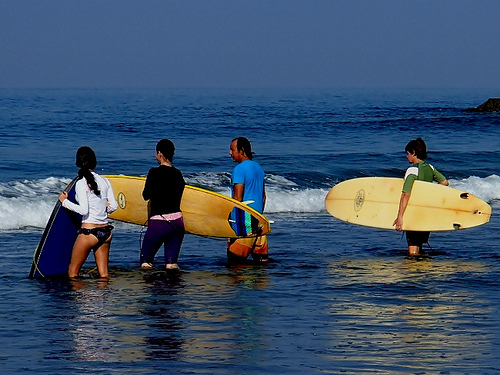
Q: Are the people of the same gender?
A: No, they are both male and female.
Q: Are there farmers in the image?
A: No, there are no farmers.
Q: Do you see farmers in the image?
A: No, there are no farmers.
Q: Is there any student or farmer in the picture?
A: No, there are no farmers or students.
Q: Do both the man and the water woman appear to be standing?
A: Yes, both the man and the woman are standing.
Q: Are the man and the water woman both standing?
A: Yes, both the man and the woman are standing.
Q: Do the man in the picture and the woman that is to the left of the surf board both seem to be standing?
A: Yes, both the man and the woman are standing.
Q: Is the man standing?
A: Yes, the man is standing.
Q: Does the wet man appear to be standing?
A: Yes, the man is standing.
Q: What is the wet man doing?
A: The man is standing.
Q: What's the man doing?
A: The man is standing.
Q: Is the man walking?
A: No, the man is standing.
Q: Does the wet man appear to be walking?
A: No, the man is standing.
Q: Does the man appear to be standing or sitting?
A: The man is standing.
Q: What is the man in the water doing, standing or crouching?
A: The man is standing.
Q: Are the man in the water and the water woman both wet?
A: Yes, both the man and the woman are wet.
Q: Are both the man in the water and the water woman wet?
A: Yes, both the man and the woman are wet.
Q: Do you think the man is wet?
A: Yes, the man is wet.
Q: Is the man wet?
A: Yes, the man is wet.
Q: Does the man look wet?
A: Yes, the man is wet.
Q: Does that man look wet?
A: Yes, the man is wet.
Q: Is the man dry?
A: No, the man is wet.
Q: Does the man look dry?
A: No, the man is wet.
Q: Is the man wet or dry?
A: The man is wet.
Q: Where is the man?
A: The man is in the water.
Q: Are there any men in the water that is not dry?
A: Yes, there is a man in the water.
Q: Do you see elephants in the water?
A: No, there is a man in the water.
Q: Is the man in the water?
A: Yes, the man is in the water.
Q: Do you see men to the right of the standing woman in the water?
A: Yes, there is a man to the right of the woman.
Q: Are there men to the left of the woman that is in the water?
A: No, the man is to the right of the woman.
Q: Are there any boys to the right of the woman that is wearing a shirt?
A: No, there is a man to the right of the woman.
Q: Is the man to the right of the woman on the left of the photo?
A: Yes, the man is to the right of the woman.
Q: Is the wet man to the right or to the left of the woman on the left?
A: The man is to the right of the woman.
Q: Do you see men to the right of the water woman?
A: Yes, there is a man to the right of the woman.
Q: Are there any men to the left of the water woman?
A: No, the man is to the right of the woman.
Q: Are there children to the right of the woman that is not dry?
A: No, there is a man to the right of the woman.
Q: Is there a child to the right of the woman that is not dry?
A: No, there is a man to the right of the woman.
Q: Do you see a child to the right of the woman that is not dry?
A: No, there is a man to the right of the woman.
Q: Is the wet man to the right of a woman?
A: Yes, the man is to the right of a woman.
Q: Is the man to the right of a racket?
A: No, the man is to the right of a woman.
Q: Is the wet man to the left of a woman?
A: No, the man is to the right of a woman.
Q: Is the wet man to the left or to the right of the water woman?
A: The man is to the right of the woman.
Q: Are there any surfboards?
A: Yes, there is a surfboard.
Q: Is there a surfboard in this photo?
A: Yes, there is a surfboard.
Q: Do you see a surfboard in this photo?
A: Yes, there is a surfboard.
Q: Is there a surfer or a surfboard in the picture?
A: Yes, there is a surfboard.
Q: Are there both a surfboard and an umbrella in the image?
A: No, there is a surfboard but no umbrellas.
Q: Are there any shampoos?
A: No, there are no shampoos.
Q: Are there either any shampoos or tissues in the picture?
A: No, there are no shampoos or tissues.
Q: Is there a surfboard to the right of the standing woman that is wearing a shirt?
A: Yes, there is a surfboard to the right of the woman.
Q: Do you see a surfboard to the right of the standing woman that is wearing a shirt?
A: Yes, there is a surfboard to the right of the woman.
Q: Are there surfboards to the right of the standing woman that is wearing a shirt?
A: Yes, there is a surfboard to the right of the woman.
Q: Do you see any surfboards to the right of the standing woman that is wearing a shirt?
A: Yes, there is a surfboard to the right of the woman.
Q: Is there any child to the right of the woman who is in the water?
A: No, there is a surfboard to the right of the woman.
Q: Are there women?
A: Yes, there is a woman.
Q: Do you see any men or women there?
A: Yes, there is a woman.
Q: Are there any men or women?
A: Yes, there is a woman.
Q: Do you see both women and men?
A: Yes, there are both a woman and a man.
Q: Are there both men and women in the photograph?
A: Yes, there are both a woman and a man.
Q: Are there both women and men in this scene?
A: Yes, there are both a woman and a man.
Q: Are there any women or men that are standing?
A: Yes, the woman is standing.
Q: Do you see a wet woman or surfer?
A: Yes, there is a wet woman.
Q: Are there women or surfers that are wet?
A: Yes, the woman is wet.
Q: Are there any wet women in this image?
A: Yes, there is a wet woman.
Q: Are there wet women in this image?
A: Yes, there is a wet woman.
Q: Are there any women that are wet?
A: Yes, there is a woman that is wet.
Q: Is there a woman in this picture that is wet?
A: Yes, there is a woman that is wet.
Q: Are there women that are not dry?
A: Yes, there is a wet woman.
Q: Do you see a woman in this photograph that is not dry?
A: Yes, there is a wet woman.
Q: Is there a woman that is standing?
A: Yes, there is a woman that is standing.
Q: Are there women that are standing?
A: Yes, there is a woman that is standing.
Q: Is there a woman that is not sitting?
A: Yes, there is a woman that is standing.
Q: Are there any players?
A: No, there are no players.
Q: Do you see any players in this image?
A: No, there are no players.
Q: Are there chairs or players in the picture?
A: No, there are no players or chairs.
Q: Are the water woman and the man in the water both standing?
A: Yes, both the woman and the man are standing.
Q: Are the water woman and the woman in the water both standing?
A: Yes, both the woman and the woman are standing.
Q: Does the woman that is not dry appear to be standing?
A: Yes, the woman is standing.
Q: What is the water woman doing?
A: The woman is standing.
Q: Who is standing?
A: The woman is standing.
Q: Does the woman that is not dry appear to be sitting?
A: No, the woman is standing.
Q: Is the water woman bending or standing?
A: The woman is standing.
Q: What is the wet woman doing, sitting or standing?
A: The woman is standing.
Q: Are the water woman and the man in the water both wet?
A: Yes, both the woman and the man are wet.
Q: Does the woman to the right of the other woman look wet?
A: Yes, the woman is wet.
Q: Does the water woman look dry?
A: No, the woman is wet.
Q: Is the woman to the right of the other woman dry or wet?
A: The woman is wet.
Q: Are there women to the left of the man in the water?
A: Yes, there is a woman to the left of the man.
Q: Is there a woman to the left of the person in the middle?
A: Yes, there is a woman to the left of the man.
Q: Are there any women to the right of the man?
A: No, the woman is to the left of the man.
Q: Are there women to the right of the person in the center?
A: No, the woman is to the left of the man.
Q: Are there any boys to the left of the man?
A: No, there is a woman to the left of the man.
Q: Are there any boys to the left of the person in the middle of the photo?
A: No, there is a woman to the left of the man.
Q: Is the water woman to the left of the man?
A: Yes, the woman is to the left of the man.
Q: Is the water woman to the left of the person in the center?
A: Yes, the woman is to the left of the man.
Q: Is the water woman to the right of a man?
A: No, the woman is to the left of a man.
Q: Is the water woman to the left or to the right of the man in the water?
A: The woman is to the left of the man.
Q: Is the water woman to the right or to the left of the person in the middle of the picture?
A: The woman is to the left of the man.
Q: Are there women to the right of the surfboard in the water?
A: Yes, there is a woman to the right of the surf board.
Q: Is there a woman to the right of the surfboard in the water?
A: Yes, there is a woman to the right of the surf board.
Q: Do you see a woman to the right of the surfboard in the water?
A: Yes, there is a woman to the right of the surf board.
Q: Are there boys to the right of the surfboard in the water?
A: No, there is a woman to the right of the surfboard.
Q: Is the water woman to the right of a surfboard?
A: Yes, the woman is to the right of a surfboard.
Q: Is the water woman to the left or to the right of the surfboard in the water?
A: The woman is to the right of the surfboard.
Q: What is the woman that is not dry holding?
A: The woman is holding the surf board.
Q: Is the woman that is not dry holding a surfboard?
A: Yes, the woman is holding a surfboard.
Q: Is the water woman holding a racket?
A: No, the woman is holding a surfboard.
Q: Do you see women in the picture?
A: Yes, there is a woman.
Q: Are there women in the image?
A: Yes, there is a woman.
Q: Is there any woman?
A: Yes, there is a woman.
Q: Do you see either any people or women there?
A: Yes, there is a woman.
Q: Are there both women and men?
A: Yes, there are both a woman and a man.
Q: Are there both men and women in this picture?
A: Yes, there are both a woman and a man.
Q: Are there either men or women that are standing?
A: Yes, the woman is standing.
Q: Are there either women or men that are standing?
A: Yes, the woman is standing.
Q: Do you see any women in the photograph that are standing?
A: Yes, there is a woman that is standing.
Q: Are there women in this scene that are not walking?
A: Yes, there is a woman that is standing.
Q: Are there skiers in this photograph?
A: No, there are no skiers.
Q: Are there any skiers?
A: No, there are no skiers.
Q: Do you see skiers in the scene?
A: No, there are no skiers.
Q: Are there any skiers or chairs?
A: No, there are no skiers or chairs.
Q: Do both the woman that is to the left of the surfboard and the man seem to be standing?
A: Yes, both the woman and the man are standing.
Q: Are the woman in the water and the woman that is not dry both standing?
A: Yes, both the woman and the woman are standing.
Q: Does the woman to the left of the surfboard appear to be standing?
A: Yes, the woman is standing.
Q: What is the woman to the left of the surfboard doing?
A: The woman is standing.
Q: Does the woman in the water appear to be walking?
A: No, the woman is standing.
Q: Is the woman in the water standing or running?
A: The woman is standing.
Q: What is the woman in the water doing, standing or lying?
A: The woman is standing.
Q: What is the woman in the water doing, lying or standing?
A: The woman is standing.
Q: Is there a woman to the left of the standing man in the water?
A: Yes, there is a woman to the left of the man.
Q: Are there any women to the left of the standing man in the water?
A: Yes, there is a woman to the left of the man.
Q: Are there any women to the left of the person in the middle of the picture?
A: Yes, there is a woman to the left of the man.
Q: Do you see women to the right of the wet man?
A: No, the woman is to the left of the man.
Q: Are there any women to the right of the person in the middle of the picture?
A: No, the woman is to the left of the man.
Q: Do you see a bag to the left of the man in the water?
A: No, there is a woman to the left of the man.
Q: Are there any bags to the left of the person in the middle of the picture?
A: No, there is a woman to the left of the man.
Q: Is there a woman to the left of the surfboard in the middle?
A: Yes, there is a woman to the left of the surfboard.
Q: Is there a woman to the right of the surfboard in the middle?
A: No, the woman is to the left of the surfboard.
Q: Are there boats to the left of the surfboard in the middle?
A: No, there is a woman to the left of the surfboard.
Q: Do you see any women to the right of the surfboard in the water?
A: Yes, there is a woman to the right of the surf board.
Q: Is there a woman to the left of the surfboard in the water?
A: No, the woman is to the right of the surfboard.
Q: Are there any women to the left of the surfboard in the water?
A: No, the woman is to the right of the surfboard.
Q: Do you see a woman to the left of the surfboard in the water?
A: No, the woman is to the right of the surfboard.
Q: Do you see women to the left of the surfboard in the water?
A: No, the woman is to the right of the surfboard.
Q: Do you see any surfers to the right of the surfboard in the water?
A: No, there is a woman to the right of the surfboard.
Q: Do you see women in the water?
A: Yes, there is a woman in the water.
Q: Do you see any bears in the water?
A: No, there is a woman in the water.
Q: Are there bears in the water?
A: No, there is a woman in the water.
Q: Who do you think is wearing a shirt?
A: The woman is wearing a shirt.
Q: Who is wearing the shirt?
A: The woman is wearing a shirt.